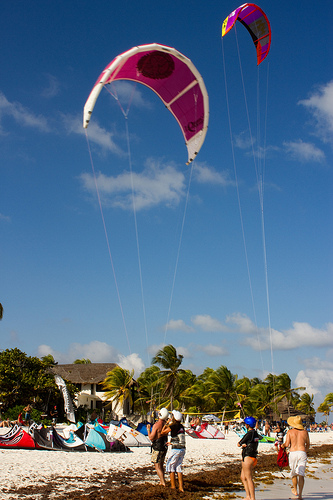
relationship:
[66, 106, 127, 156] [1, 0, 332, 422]
cloud in sky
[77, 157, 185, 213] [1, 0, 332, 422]
cloud in sky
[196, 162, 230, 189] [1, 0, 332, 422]
cloud in sky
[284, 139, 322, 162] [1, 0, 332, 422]
cloud in sky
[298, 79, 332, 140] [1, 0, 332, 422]
cloud in sky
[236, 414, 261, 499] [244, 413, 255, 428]
woman wearing helmet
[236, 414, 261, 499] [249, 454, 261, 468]
woman wearing bikini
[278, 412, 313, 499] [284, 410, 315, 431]
man wearing hat